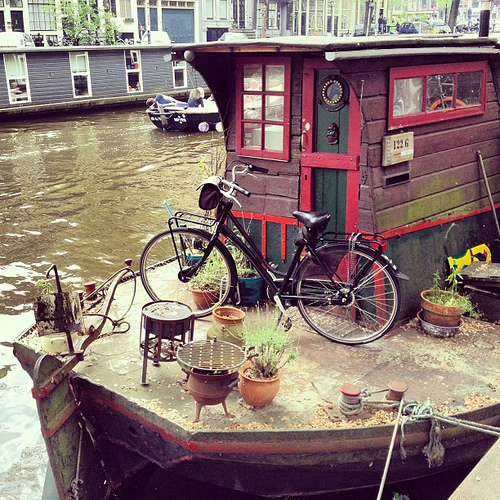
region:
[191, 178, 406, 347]
this is a bicycle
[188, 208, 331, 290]
the bicycle is parked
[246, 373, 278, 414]
this is a pot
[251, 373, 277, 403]
the pot is brown in color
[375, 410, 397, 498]
this is a rope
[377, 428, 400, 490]
the rope is white in color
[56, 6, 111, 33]
this is a tree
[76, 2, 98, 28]
the leaves are green in color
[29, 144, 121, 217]
this is a water body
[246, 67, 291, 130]
this is the window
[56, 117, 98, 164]
this is the water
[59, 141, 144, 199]
the water has ripples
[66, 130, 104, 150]
the water is blue in color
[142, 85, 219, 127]
this is a boat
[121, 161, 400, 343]
this is a bicycle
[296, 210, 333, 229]
this is a seat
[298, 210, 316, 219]
the seat is black in color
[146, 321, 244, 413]
these are two stoves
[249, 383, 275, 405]
this is a pot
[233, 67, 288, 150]
this is a window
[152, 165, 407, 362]
the biycle is black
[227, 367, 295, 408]
the pot is made of clay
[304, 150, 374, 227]
the building is painted red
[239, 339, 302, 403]
the plant is growing in the pot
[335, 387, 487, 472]
the boat is tied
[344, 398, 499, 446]
the rope is white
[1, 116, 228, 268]
the water is clear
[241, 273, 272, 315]
the bucket is blue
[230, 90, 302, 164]
the building ha s window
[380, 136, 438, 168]
the numbers are 1226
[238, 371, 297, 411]
this is a pot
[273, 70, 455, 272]
this is a structure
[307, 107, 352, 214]
this is a door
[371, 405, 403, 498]
this is a rope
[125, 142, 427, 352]
the bike is black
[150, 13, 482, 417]
a house on a boat